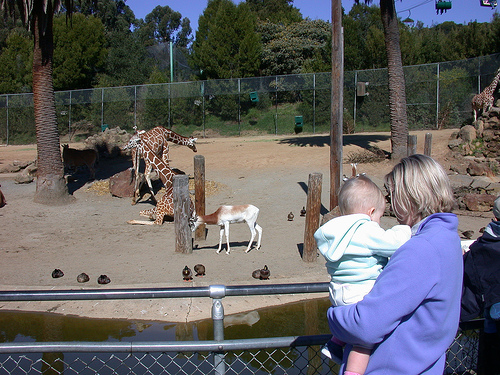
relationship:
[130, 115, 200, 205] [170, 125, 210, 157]
giraffe has head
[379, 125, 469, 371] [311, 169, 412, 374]
mother holding baby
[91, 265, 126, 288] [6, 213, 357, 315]
duck on top of ground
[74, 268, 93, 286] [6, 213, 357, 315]
duck on top of ground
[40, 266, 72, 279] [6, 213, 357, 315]
duck on top of ground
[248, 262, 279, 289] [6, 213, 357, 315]
duck on top of ground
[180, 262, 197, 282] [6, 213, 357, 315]
duck on top of ground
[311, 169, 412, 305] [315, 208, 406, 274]
baby has hoodie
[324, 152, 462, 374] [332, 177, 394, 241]
mother has head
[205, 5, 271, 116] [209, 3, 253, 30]
tree has top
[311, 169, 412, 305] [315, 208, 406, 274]
baby wearing hoodie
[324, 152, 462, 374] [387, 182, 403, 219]
mother wearing glasses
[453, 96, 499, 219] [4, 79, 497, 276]
rocks are inside of animal area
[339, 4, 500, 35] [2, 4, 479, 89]
lift inside of background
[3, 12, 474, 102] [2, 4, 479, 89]
trees are inside of background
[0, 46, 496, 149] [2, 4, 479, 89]
fence inside of background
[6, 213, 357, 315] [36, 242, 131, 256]
ground made of dirt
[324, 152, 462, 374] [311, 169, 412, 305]
mother holding baby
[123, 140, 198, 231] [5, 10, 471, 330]
giraffe inside of zoo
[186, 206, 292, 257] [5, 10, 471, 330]
deer inside of zoo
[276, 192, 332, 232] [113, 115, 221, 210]
pigeons hanging around griaffes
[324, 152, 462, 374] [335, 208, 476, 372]
mother wearing sweater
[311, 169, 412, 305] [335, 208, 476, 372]
baby wearing sweater